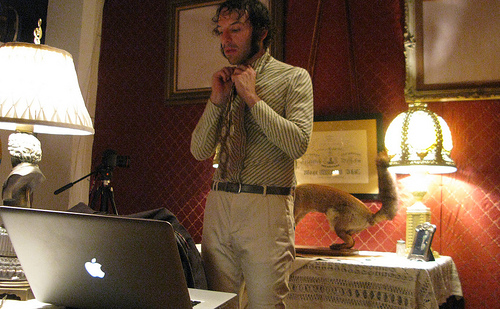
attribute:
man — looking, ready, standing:
[201, 10, 316, 263]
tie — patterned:
[222, 115, 250, 151]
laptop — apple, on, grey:
[9, 206, 182, 299]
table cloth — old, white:
[369, 248, 413, 290]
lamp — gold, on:
[385, 108, 453, 176]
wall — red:
[310, 37, 396, 103]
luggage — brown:
[166, 212, 201, 244]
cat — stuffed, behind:
[326, 192, 376, 235]